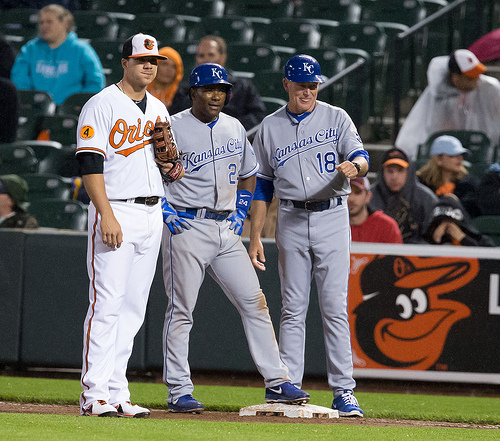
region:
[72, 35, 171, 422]
an Oriols baseball player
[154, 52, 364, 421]
two Kansas city baseball players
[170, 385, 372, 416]
blue nike tennis shoes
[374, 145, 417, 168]
a fans team hat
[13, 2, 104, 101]
a woman sitting in the stands wearing a blue hoodie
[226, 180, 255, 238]
blue gloves on one of the players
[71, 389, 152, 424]
white tennis shoes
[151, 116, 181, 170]
a catchers mitt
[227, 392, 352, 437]
one of the bases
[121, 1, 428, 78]
empty chairs in the stands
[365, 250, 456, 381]
The Baltimore Orioles logo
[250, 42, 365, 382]
The first base coach for Kansas City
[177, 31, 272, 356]
The runner on first base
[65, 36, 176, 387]
The first basemen for Baltimore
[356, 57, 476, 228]
Fans in the stands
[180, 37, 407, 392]
Kansas City Royals players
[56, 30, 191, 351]
Baltimore Orioles player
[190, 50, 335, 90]
Kansas City batting helmits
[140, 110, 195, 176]
First baseman's glove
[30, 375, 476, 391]
Foul territory on the field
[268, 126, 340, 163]
Team insignia on baseball jersey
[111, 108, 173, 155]
Team insignia on baseball jersey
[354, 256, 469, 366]
Team insignia on baseball park wall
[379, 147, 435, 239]
Spectator sitting in the stands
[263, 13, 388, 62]
Empty seats in the baseball stadium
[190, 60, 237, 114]
Batting helmet worn by baserunner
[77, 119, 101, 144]
Baseball players number on sleeve of uniform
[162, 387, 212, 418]
Cleats worn by baseball players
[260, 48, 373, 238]
First base coach giving advice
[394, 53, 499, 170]
Rain poncho worn by spectator at baseball game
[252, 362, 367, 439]
the shoes is blue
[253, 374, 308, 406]
the shoes is blue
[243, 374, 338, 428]
the shoes is blue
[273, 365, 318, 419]
the shoes is blue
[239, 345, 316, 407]
the shoes is blue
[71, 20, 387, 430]
group of three baseball players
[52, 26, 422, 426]
three men standing on baseball field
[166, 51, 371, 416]
two men wearing blue helmets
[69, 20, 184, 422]
one man wearing orange black and white cap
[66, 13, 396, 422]
three men wearing baseball uniforms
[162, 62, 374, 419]
two men wearing grey and blue outfits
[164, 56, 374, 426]
two men wearing blue shoes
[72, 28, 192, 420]
man wearing white and orange baseball uniform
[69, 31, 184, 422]
man holding catchers mitt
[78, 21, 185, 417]
man wearing white shoes